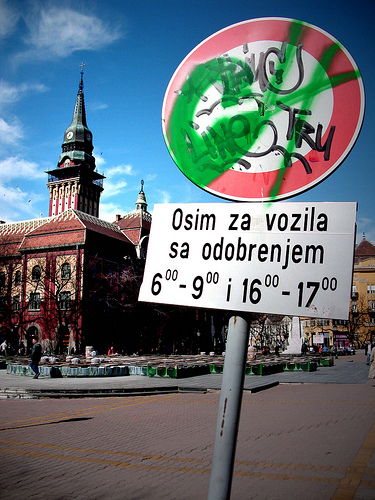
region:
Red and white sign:
[135, 10, 368, 199]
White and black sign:
[118, 151, 361, 337]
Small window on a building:
[54, 262, 77, 283]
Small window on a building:
[51, 287, 73, 316]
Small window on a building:
[26, 259, 43, 286]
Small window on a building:
[20, 291, 45, 309]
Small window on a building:
[10, 263, 27, 288]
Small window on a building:
[8, 287, 29, 314]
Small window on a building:
[47, 321, 83, 366]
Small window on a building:
[365, 279, 374, 294]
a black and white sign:
[135, 201, 365, 322]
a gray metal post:
[210, 320, 250, 496]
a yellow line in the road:
[4, 394, 156, 436]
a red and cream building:
[3, 65, 155, 352]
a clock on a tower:
[64, 129, 75, 138]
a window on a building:
[30, 293, 41, 311]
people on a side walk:
[28, 336, 41, 378]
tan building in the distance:
[339, 244, 373, 357]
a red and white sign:
[164, 17, 361, 203]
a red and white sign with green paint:
[164, 16, 365, 199]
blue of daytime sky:
[0, 0, 371, 212]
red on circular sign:
[160, 15, 365, 203]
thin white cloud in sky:
[0, 1, 129, 71]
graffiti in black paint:
[179, 41, 334, 178]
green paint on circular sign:
[164, 18, 354, 195]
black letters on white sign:
[138, 201, 357, 322]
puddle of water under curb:
[0, 386, 202, 399]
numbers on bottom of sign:
[150, 269, 340, 318]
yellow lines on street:
[2, 395, 373, 495]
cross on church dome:
[63, 61, 91, 144]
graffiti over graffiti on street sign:
[156, 15, 371, 202]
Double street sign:
[141, 13, 356, 319]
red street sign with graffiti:
[160, 12, 370, 202]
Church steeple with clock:
[48, 56, 100, 148]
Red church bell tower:
[33, 145, 101, 210]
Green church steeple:
[34, 53, 94, 158]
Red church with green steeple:
[1, 52, 108, 357]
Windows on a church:
[7, 211, 90, 364]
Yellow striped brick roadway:
[5, 386, 374, 489]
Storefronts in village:
[284, 316, 374, 389]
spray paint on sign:
[60, 0, 371, 280]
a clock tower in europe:
[36, 42, 151, 365]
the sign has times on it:
[85, 155, 370, 346]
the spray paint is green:
[137, 51, 367, 284]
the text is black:
[152, 31, 362, 207]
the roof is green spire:
[28, 51, 118, 315]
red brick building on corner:
[24, 60, 136, 321]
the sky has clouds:
[34, 10, 174, 196]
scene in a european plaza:
[45, 40, 334, 410]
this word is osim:
[162, 194, 217, 234]